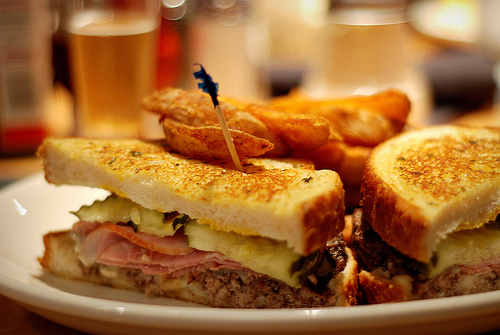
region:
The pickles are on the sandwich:
[77, 191, 303, 266]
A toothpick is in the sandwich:
[192, 60, 247, 174]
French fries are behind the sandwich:
[150, 75, 395, 170]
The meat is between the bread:
[68, 233, 333, 299]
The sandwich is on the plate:
[38, 136, 497, 303]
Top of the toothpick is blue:
[192, 60, 221, 108]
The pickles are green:
[75, 190, 317, 285]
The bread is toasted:
[43, 142, 498, 217]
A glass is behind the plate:
[70, 3, 155, 138]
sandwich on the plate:
[49, 150, 352, 292]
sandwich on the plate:
[59, 150, 337, 295]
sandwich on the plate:
[37, 142, 334, 298]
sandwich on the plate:
[67, 154, 314, 302]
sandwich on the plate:
[35, 158, 318, 290]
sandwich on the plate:
[56, 168, 312, 293]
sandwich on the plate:
[32, 163, 309, 290]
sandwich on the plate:
[40, 158, 322, 294]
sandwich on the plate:
[19, 137, 339, 302]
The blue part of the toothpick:
[195, 66, 220, 107]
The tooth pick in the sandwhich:
[197, 63, 254, 174]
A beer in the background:
[67, 11, 169, 143]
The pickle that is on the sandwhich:
[93, 191, 324, 282]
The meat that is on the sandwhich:
[83, 222, 235, 289]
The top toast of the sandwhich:
[109, 113, 304, 237]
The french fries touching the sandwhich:
[166, 83, 256, 168]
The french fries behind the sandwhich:
[163, 91, 415, 181]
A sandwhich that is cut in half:
[72, 103, 483, 291]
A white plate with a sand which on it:
[7, 159, 489, 333]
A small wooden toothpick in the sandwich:
[190, 62, 245, 172]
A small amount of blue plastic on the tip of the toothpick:
[192, 63, 224, 110]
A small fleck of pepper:
[172, 158, 183, 168]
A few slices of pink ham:
[79, 220, 229, 282]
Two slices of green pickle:
[185, 222, 328, 287]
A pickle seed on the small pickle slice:
[129, 205, 142, 227]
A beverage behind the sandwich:
[70, 0, 158, 135]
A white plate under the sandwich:
[0, 180, 67, 305]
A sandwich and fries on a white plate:
[7, 88, 497, 330]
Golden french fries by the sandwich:
[145, 68, 399, 173]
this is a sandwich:
[12, 105, 499, 310]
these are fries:
[152, 55, 424, 178]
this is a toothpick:
[186, 49, 268, 175]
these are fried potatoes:
[155, 47, 421, 189]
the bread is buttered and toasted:
[340, 102, 498, 233]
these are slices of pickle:
[75, 187, 341, 284]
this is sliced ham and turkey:
[52, 220, 230, 283]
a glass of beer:
[57, 4, 181, 149]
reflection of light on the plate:
[12, 187, 53, 222]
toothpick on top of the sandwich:
[185, 59, 252, 170]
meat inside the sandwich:
[110, 226, 162, 269]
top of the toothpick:
[190, 61, 222, 110]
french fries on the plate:
[261, 107, 340, 154]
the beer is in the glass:
[69, 2, 154, 144]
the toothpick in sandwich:
[191, 66, 251, 178]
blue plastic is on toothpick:
[194, 66, 225, 109]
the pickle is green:
[187, 220, 322, 291]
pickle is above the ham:
[76, 198, 212, 277]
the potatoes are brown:
[177, 87, 395, 152]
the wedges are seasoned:
[185, 96, 381, 160]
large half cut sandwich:
[38, 136, 360, 311]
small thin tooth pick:
[194, 61, 243, 168]